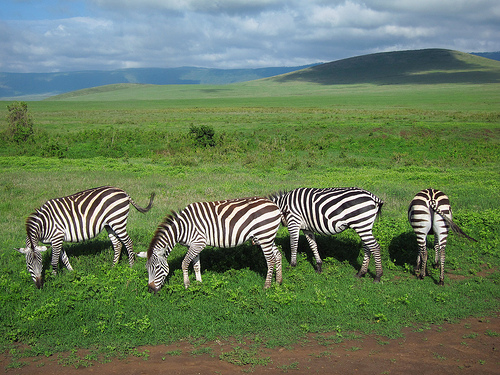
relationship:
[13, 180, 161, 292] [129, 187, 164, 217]
zebra has tail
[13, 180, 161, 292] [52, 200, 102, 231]
zebra has stripes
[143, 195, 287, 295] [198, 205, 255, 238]
zebra has stripes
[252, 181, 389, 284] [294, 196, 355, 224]
zebra has stripes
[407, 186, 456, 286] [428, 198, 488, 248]
zebra has tail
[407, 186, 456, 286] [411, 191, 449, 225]
zebra has stripes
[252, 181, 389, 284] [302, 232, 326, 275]
zebra has leg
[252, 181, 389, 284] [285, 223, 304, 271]
zebra has leg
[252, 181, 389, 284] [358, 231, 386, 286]
zebra has leg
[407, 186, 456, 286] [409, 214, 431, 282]
zebra has leg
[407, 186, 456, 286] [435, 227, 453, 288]
zebra has leg